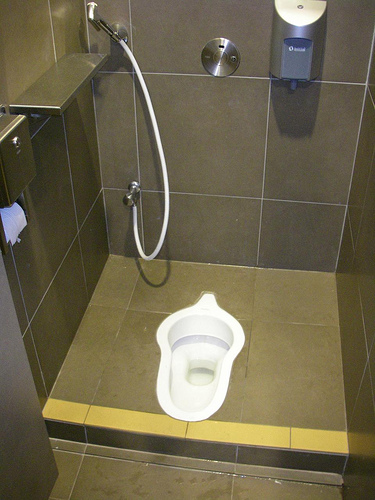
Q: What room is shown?
A: It is a bathroom.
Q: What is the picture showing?
A: It is showing a bathroom.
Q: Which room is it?
A: It is a bathroom.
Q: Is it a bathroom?
A: Yes, it is a bathroom.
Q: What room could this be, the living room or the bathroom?
A: It is the bathroom.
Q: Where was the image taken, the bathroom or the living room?
A: It was taken at the bathroom.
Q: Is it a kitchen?
A: No, it is a bathroom.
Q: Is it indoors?
A: Yes, it is indoors.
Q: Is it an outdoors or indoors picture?
A: It is indoors.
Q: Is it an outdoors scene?
A: No, it is indoors.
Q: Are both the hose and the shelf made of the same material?
A: Yes, both the hose and the shelf are made of metal.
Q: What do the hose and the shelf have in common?
A: The material, both the hose and the shelf are metallic.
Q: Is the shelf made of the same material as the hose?
A: Yes, both the shelf and the hose are made of metal.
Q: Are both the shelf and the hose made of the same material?
A: Yes, both the shelf and the hose are made of metal.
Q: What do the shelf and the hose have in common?
A: The material, both the shelf and the hose are metallic.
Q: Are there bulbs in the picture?
A: No, there are no bulbs.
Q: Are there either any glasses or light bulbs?
A: No, there are no light bulbs or glasses.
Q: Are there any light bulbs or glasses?
A: No, there are no light bulbs or glasses.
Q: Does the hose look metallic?
A: Yes, the hose is metallic.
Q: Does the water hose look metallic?
A: Yes, the water hose is metallic.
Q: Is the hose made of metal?
A: Yes, the hose is made of metal.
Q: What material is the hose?
A: The hose is made of metal.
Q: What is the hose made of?
A: The hose is made of metal.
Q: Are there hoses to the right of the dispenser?
A: Yes, there is a hose to the right of the dispenser.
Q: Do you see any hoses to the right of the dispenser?
A: Yes, there is a hose to the right of the dispenser.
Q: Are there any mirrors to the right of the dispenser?
A: No, there is a hose to the right of the dispenser.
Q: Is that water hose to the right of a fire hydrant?
A: No, the water hose is to the right of the dispenser.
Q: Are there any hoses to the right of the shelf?
A: Yes, there is a hose to the right of the shelf.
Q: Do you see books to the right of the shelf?
A: No, there is a hose to the right of the shelf.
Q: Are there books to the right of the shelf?
A: No, there is a hose to the right of the shelf.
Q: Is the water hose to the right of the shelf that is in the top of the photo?
A: Yes, the water hose is to the right of the shelf.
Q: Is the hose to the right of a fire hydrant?
A: No, the hose is to the right of the shelf.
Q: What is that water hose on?
A: The water hose is on the wall.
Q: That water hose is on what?
A: The water hose is on the wall.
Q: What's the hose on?
A: The water hose is on the wall.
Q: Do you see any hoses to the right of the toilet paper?
A: Yes, there is a hose to the right of the toilet paper.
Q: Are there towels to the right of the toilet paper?
A: No, there is a hose to the right of the toilet paper.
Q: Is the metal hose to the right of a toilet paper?
A: Yes, the water hose is to the right of a toilet paper.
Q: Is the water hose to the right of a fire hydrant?
A: No, the water hose is to the right of a toilet paper.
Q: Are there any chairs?
A: No, there are no chairs.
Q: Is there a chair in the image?
A: No, there are no chairs.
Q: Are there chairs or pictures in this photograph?
A: No, there are no chairs or pictures.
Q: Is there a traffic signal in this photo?
A: No, there are no traffic lights.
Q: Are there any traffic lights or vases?
A: No, there are no traffic lights or vases.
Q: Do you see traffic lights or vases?
A: No, there are no traffic lights or vases.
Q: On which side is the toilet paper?
A: The toilet paper is on the left of the image.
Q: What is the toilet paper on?
A: The toilet paper is on the wall.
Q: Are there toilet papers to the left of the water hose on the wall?
A: Yes, there is a toilet paper to the left of the hose.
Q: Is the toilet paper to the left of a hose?
A: Yes, the toilet paper is to the left of a hose.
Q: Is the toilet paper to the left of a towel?
A: No, the toilet paper is to the left of a hose.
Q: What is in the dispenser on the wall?
A: The toilet paper is in the dispenser.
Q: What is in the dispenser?
A: The toilet paper is in the dispenser.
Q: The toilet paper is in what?
A: The toilet paper is in the dispenser.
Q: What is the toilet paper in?
A: The toilet paper is in the dispenser.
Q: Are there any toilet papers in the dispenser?
A: Yes, there is a toilet paper in the dispenser.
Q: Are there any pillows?
A: No, there are no pillows.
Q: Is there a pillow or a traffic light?
A: No, there are no pillows or traffic lights.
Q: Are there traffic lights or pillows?
A: No, there are no pillows or traffic lights.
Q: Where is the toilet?
A: The toilet is in the bathroom.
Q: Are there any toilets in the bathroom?
A: Yes, there is a toilet in the bathroom.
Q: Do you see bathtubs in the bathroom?
A: No, there is a toilet in the bathroom.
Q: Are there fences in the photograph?
A: No, there are no fences.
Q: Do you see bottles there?
A: No, there are no bottles.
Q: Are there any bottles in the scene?
A: No, there are no bottles.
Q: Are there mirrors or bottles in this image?
A: No, there are no bottles or mirrors.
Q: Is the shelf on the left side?
A: Yes, the shelf is on the left of the image.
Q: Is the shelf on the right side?
A: No, the shelf is on the left of the image.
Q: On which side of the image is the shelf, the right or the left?
A: The shelf is on the left of the image.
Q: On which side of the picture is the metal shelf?
A: The shelf is on the left of the image.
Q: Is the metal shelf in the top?
A: Yes, the shelf is in the top of the image.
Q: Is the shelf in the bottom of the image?
A: No, the shelf is in the top of the image.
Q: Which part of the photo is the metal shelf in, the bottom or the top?
A: The shelf is in the top of the image.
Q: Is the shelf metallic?
A: Yes, the shelf is metallic.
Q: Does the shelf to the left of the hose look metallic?
A: Yes, the shelf is metallic.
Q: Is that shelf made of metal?
A: Yes, the shelf is made of metal.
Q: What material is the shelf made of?
A: The shelf is made of metal.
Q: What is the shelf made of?
A: The shelf is made of metal.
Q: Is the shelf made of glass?
A: No, the shelf is made of metal.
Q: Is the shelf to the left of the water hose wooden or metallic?
A: The shelf is metallic.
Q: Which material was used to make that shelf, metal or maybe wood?
A: The shelf is made of metal.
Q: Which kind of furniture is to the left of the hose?
A: The piece of furniture is a shelf.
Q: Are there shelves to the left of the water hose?
A: Yes, there is a shelf to the left of the water hose.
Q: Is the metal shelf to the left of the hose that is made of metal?
A: Yes, the shelf is to the left of the hose.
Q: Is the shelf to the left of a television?
A: No, the shelf is to the left of the hose.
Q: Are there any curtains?
A: No, there are no curtains.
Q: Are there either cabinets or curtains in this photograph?
A: No, there are no curtains or cabinets.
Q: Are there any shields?
A: No, there are no shields.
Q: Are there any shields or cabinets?
A: No, there are no shields or cabinets.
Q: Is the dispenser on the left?
A: Yes, the dispenser is on the left of the image.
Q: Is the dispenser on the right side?
A: No, the dispenser is on the left of the image.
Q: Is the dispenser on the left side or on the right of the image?
A: The dispenser is on the left of the image.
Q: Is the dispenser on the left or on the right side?
A: The dispenser is on the left of the image.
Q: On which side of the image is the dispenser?
A: The dispenser is on the left of the image.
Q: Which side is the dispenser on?
A: The dispenser is on the left of the image.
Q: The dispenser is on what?
A: The dispenser is on the wall.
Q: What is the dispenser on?
A: The dispenser is on the wall.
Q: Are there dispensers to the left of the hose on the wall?
A: Yes, there is a dispenser to the left of the water hose.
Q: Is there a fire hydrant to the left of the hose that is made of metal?
A: No, there is a dispenser to the left of the hose.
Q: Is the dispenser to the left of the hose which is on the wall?
A: Yes, the dispenser is to the left of the hose.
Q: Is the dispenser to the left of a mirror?
A: No, the dispenser is to the left of the hose.